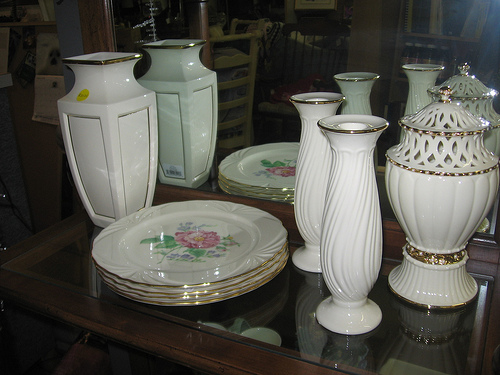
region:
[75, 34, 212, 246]
white vases on table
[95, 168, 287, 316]
white plates are stacked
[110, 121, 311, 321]
white plates are circular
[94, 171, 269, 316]
white gilded china plates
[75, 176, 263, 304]
plates have floral pattern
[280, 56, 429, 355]
four tall white vases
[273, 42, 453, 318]
white vases are circular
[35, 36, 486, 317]
containers on glass-top table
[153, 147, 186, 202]
bar code on rear of vase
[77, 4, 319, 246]
mirror behind vases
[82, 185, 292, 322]
stack of plates on table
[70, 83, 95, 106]
yellow sticker on vase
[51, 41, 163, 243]
vase beside plates on table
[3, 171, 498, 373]
table next to mirror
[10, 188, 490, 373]
table has glass top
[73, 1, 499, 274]
mirror behind glass table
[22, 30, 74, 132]
calendar hanging on wall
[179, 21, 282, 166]
chair reflection in mirror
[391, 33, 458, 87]
bottles in reflection in mirror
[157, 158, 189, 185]
white barcode sticker on vase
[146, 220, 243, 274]
design on white dinner plate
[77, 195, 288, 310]
stack of white dinner plates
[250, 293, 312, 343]
glass top on table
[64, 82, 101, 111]
yellow sticker on side of white vase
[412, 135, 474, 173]
design on white vase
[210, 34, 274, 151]
tan dining chair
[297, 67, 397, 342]
white vases on glass table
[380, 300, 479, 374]
reflection of white vase on glass table top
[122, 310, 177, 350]
brown trim of table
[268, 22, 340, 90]
dark brown dining chair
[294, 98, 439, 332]
white vase on table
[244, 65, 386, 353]
white vase on table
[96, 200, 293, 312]
a stack of white plates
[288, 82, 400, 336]
a pair of white vases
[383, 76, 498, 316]
a white urn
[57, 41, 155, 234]
a white vase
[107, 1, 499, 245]
a mirror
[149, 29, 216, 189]
reflection of a white vase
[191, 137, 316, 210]
reflection of a stack of plates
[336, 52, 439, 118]
reflection of a pair of white vases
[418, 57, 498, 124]
reflection of a white urn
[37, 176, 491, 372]
a glass display case